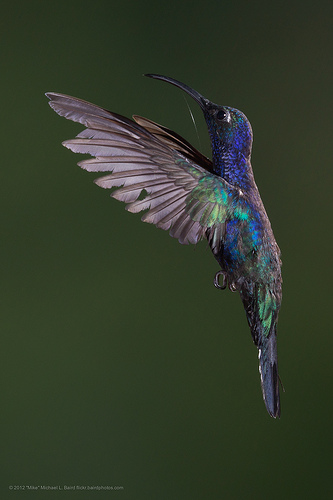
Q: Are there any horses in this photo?
A: No, there are no horses.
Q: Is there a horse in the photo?
A: No, there are no horses.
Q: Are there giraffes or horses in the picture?
A: No, there are no horses or giraffes.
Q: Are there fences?
A: No, there are no fences.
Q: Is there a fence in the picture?
A: No, there are no fences.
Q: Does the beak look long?
A: Yes, the beak is long.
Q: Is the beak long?
A: Yes, the beak is long.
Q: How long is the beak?
A: The beak is long.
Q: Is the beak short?
A: No, the beak is long.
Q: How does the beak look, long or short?
A: The beak is long.